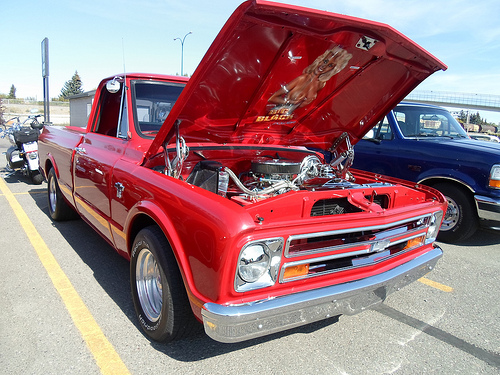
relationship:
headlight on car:
[422, 211, 444, 246] [37, 7, 446, 348]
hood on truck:
[138, 1, 448, 169] [37, 2, 459, 358]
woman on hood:
[263, 38, 355, 124] [138, 1, 448, 169]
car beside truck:
[350, 100, 500, 243] [37, 2, 459, 358]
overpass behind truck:
[399, 83, 498, 116] [348, 97, 498, 241]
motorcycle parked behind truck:
[0, 113, 46, 184] [37, 2, 459, 358]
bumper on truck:
[187, 239, 442, 350] [37, 2, 459, 358]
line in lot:
[2, 184, 132, 373] [1, 144, 498, 372]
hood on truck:
[138, 1, 454, 176] [37, 2, 459, 358]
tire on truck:
[124, 215, 201, 354] [37, 2, 459, 358]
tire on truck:
[40, 163, 80, 224] [37, 2, 459, 358]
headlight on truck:
[234, 238, 285, 291] [37, 2, 459, 358]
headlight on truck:
[426, 211, 437, 249] [37, 2, 459, 358]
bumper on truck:
[201, 244, 442, 344] [37, 2, 459, 358]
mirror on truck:
[103, 70, 123, 96] [37, 2, 459, 358]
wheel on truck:
[422, 179, 487, 251] [342, 92, 498, 249]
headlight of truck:
[234, 238, 285, 291] [34, 38, 453, 349]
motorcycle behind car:
[16, 100, 64, 216] [38, 0, 446, 344]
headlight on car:
[213, 175, 378, 310] [63, 37, 465, 319]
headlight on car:
[234, 238, 285, 291] [70, 21, 432, 363]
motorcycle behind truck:
[0, 113, 46, 184] [19, 10, 446, 331]